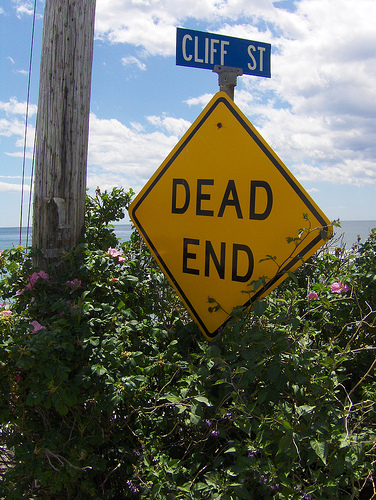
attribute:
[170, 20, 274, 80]
sign — blue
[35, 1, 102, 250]
pole — utility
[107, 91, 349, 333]
sign — yellow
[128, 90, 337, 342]
telephone pole — beside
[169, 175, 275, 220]
letters — black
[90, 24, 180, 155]
sky — blue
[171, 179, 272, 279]
letters — black, white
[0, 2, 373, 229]
blue — cloudy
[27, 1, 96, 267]
utility pole — wooden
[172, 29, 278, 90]
sign — cliff, street, identification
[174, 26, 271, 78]
street sign — blue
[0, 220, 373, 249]
water — distant, blue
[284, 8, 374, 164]
clouds — white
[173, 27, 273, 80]
sign — white, blue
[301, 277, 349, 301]
flowers — pink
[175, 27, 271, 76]
blue sign — rectangular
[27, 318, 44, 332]
flowers — pink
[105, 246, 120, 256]
flowers — pink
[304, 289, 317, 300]
flowers — pink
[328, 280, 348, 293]
flowers — pink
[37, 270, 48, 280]
flowers — pink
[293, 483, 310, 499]
flowers — purple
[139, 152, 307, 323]
sign — diamond shaped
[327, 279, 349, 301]
pink flower — blooming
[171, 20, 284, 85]
sign — white, blue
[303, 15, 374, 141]
clouds — white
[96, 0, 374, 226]
sky — blue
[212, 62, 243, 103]
pole — holding, metal, grey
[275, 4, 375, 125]
clouds — white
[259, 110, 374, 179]
clouds — white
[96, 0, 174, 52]
clouds — white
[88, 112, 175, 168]
clouds — white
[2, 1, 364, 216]
sky — blue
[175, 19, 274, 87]
sign — blue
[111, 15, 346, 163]
sky — blue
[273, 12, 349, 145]
clouds — white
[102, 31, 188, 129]
sky — blue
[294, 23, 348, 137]
clouds — white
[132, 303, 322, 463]
bush — green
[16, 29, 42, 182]
wire — metal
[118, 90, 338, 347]
sign — rhombus, yellow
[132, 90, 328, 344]
sign — yellow, black, road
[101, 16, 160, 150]
sky — blue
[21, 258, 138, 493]
shadow — utility, pole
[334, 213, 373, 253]
ocean — blue, background, photo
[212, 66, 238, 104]
post — top, metal, sign